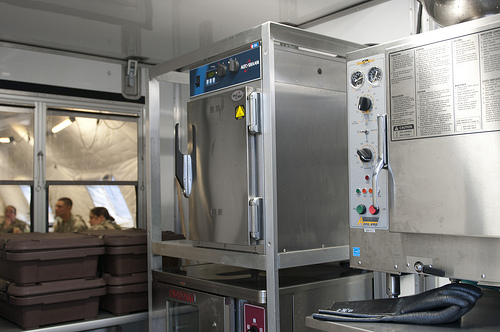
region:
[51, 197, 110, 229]
Two people next to each other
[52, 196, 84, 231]
A man seated on a chair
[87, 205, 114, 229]
A woman sitting down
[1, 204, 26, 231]
A person sitting alone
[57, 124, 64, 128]
A suspended light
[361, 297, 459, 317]
Rubber gloves on a surface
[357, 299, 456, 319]
Black rubber gloves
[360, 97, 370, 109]
A black switch button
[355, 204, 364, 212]
A green switch button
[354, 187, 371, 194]
A bunch of switch buttons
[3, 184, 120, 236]
three people are sen through the window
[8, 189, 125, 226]
they are in the same outfits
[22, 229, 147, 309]
the boxes are brown in color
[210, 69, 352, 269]
the ftridge is silvery in color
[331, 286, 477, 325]
the handgloves are plastic material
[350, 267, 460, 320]
the handcloves atre black in color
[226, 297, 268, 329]
the poster is red in color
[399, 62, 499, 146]
tthe papers are on a white board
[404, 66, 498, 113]
the words are writn in black color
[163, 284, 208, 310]
the words are written in red color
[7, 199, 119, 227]
these are some people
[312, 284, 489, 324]
a pair of gloves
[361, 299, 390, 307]
the gloves are black in color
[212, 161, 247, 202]
the area is shiny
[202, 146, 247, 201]
the area is metallic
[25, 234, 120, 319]
these are some boxes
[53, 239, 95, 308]
the boxes are made of plastic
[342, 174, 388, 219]
these are some buttons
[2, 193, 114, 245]
soldiers in a tent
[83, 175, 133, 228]
a window on a tent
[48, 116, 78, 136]
a tubular light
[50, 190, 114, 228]
a man and woman together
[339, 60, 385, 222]
controls on a piece of equipment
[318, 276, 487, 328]
long black rubber gloves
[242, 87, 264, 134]
a hinge on a door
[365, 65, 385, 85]
analog gauges with a indicator needle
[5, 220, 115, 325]
storage bins with lids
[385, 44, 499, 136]
a label printed on stainless steel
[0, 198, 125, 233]
soldiers in uniforms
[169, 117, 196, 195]
a handle on kitchen equipment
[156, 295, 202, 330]
glass pane on the door of kitchen equipment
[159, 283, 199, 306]
a brand label on equipment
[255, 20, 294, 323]
a metal equipment frame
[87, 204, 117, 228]
a woman with black hair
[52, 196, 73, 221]
a man with short hair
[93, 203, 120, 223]
hair on a person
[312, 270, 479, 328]
two black gloves on a counter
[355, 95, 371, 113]
a black oven knob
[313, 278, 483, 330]
a pair of long black gloves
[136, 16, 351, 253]
a commercial kitchen oven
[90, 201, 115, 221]
a woman's black hair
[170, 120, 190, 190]
a black oven handle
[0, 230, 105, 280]
a brown container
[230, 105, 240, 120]
a red and black sticker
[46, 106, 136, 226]
a window of a kitchen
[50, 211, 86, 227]
a green army uniform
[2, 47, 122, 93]
a white painted wall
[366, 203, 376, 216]
round button on dishwasher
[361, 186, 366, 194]
round button on dishwasher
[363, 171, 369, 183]
round button on dishwasher